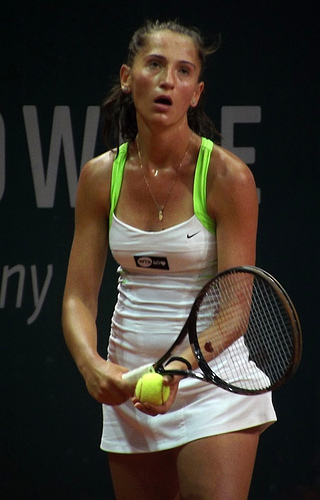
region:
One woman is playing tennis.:
[58, 50, 286, 428]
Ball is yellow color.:
[119, 368, 189, 416]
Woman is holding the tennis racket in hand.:
[77, 332, 205, 428]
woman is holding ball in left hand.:
[131, 365, 182, 419]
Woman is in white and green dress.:
[82, 159, 248, 365]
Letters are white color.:
[9, 97, 90, 186]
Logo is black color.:
[130, 252, 177, 277]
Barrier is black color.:
[18, 357, 84, 452]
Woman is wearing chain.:
[119, 137, 198, 237]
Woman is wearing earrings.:
[118, 76, 207, 124]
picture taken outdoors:
[32, 200, 303, 488]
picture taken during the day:
[1, 201, 279, 482]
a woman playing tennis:
[64, 266, 310, 468]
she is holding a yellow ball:
[112, 349, 223, 446]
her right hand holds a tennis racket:
[115, 285, 309, 435]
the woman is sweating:
[131, 126, 303, 254]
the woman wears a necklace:
[150, 206, 187, 244]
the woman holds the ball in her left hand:
[133, 365, 208, 437]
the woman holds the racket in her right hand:
[94, 333, 222, 402]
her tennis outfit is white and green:
[100, 210, 231, 268]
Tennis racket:
[119, 265, 302, 395]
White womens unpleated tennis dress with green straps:
[108, 141, 277, 436]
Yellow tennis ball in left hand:
[133, 369, 180, 415]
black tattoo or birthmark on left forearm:
[132, 321, 245, 417]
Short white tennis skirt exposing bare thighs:
[93, 406, 279, 496]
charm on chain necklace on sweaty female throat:
[133, 131, 196, 224]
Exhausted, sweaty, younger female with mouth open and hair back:
[117, 17, 210, 130]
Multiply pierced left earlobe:
[116, 62, 133, 95]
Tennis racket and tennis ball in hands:
[122, 267, 302, 406]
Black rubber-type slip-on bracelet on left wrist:
[164, 354, 196, 375]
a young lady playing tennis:
[54, 20, 299, 496]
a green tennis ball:
[127, 367, 180, 409]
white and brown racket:
[120, 264, 311, 397]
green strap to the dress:
[187, 136, 222, 226]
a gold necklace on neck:
[129, 146, 205, 222]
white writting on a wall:
[0, 245, 58, 317]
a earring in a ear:
[110, 80, 132, 97]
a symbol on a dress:
[133, 251, 170, 272]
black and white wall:
[3, 5, 113, 225]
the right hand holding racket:
[79, 355, 142, 407]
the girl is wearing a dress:
[90, 135, 282, 459]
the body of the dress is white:
[83, 212, 282, 465]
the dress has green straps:
[98, 134, 237, 241]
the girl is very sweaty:
[73, 16, 256, 226]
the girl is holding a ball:
[129, 368, 177, 414]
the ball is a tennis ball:
[128, 368, 176, 404]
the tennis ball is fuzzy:
[131, 368, 169, 405]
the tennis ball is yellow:
[128, 368, 171, 407]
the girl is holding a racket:
[117, 259, 302, 400]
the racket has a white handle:
[115, 363, 157, 384]